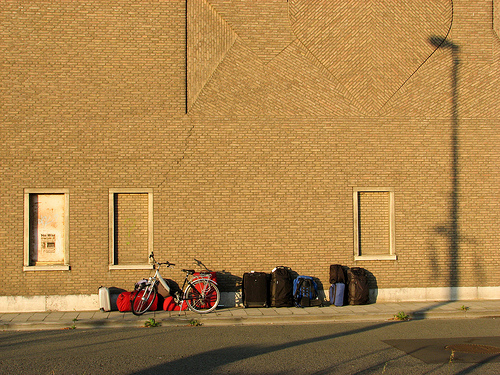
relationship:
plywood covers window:
[32, 197, 61, 261] [23, 185, 75, 279]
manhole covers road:
[395, 318, 497, 369] [14, 308, 488, 363]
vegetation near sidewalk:
[134, 318, 213, 327] [248, 288, 477, 322]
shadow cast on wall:
[434, 44, 466, 312] [40, 34, 497, 179]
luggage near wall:
[98, 256, 379, 329] [40, 34, 497, 179]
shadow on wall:
[434, 44, 466, 312] [40, 34, 497, 179]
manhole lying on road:
[395, 318, 497, 369] [14, 308, 488, 363]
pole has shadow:
[411, 30, 477, 316] [434, 44, 466, 312]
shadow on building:
[434, 44, 466, 312] [23, 14, 497, 310]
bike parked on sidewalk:
[125, 254, 228, 313] [248, 288, 477, 322]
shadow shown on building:
[434, 44, 466, 312] [23, 14, 497, 310]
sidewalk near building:
[248, 288, 477, 322] [23, 14, 497, 310]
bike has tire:
[125, 254, 228, 313] [181, 284, 217, 310]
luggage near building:
[98, 256, 379, 329] [23, 14, 497, 310]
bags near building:
[98, 256, 379, 329] [23, 14, 497, 310]